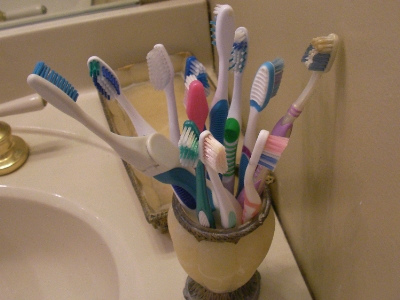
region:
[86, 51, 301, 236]
TOOTHBRUSHES ARE ABUDANT IN THIS HOUSEHOLD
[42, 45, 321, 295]
DENTISTS' HOME BATHROOMS BE LIKE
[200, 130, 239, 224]
a toothbrush in a cup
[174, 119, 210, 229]
a toothbrush in a cup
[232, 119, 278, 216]
a toothbrush in a cup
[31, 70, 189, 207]
a toothbrush in a cup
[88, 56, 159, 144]
a toothbrush in a cup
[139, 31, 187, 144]
a toothbrush in a cup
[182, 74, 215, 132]
a toothbrush in a cup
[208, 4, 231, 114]
a toothbrush in a cup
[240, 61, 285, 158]
a toothbrush in a cup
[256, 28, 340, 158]
a toothbrush in a cup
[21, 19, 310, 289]
toothbrushes in a container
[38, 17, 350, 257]
multiple kinds of toothbrushes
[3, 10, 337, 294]
white bathroom sink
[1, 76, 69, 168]
gold and white faucet handle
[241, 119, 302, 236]
pink and white toothbrush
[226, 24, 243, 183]
green and white toothbrush with blue and white bristles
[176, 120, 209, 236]
turquoise and white toothbrush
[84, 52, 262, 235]
a soap dish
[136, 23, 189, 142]
white toothbrush with white bristles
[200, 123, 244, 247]
white and light green toothbrush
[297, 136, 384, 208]
shadow cast on wall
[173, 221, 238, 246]
brown rim on container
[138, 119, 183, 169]
white base on tooth brush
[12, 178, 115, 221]
shine on white sink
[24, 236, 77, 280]
deep indent in the white sink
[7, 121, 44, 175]
base of gold faucet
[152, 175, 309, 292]
round brown cup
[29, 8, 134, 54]
edge of white wall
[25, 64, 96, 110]
blue tip of tooth brush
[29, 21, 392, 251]
container full of different color toothbrushes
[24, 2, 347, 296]
multiple toothbrushes in a cup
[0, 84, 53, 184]
white sink faucet handle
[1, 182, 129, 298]
white sink bowl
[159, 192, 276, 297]
tan bathroom cup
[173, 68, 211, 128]
pink toothbrush head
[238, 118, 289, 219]
white toothbrush with pink, white and blue bristles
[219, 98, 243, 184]
green and white handle of toothbrush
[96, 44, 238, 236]
tan and gold soap dish behind toothbrushes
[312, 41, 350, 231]
dark shadow of toothbrush on wall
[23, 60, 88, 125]
white toothbrush with blue bristles